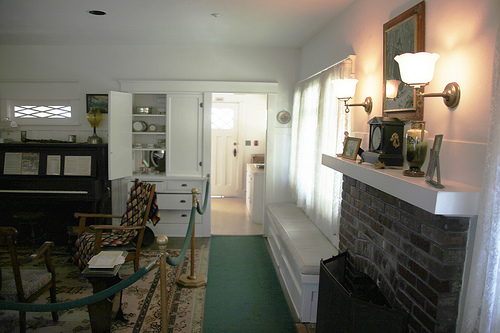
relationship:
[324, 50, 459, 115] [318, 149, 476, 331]
lights hanging above fireplace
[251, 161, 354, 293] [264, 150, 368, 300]
cushion on window bench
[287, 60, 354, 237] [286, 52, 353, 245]
curtains on window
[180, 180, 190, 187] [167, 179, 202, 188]
handle on drawer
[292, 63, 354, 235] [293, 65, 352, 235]
curtains on window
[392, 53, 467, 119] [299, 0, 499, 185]
lamp on wall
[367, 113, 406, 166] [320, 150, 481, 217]
clock on fireplace mantle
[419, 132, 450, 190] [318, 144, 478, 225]
picture frame on fireplace mantle